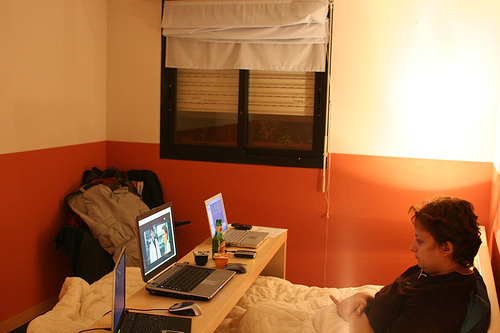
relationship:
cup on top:
[192, 249, 210, 266] [126, 222, 285, 315]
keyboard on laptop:
[160, 263, 212, 293] [138, 201, 235, 301]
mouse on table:
[169, 301, 200, 316] [117, 220, 285, 325]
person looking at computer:
[331, 197, 490, 332] [136, 199, 232, 297]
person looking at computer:
[331, 197, 490, 332] [201, 188, 267, 250]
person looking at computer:
[331, 197, 490, 332] [110, 243, 190, 331]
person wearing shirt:
[328, 195, 491, 333] [363, 263, 487, 330]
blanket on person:
[217, 272, 381, 327] [328, 195, 491, 333]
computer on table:
[110, 245, 193, 331] [110, 225, 288, 328]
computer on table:
[110, 245, 193, 331] [135, 202, 238, 298]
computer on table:
[203, 192, 269, 250] [110, 225, 288, 328]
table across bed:
[86, 179, 332, 329] [48, 228, 445, 325]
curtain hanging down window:
[160, 0, 328, 72] [142, 5, 392, 239]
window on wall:
[145, 14, 340, 194] [92, 14, 483, 274]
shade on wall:
[172, 10, 375, 103] [123, 13, 415, 270]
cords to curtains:
[322, 23, 357, 218] [143, 1, 353, 75]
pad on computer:
[187, 262, 243, 298] [139, 195, 249, 313]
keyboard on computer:
[145, 263, 237, 301] [122, 197, 243, 308]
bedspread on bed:
[44, 238, 359, 331] [59, 220, 390, 310]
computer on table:
[134, 201, 238, 302] [93, 192, 312, 328]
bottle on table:
[204, 202, 230, 263] [72, 179, 308, 329]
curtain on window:
[160, 20, 334, 97] [145, 6, 351, 185]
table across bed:
[79, 221, 287, 333] [50, 203, 439, 319]